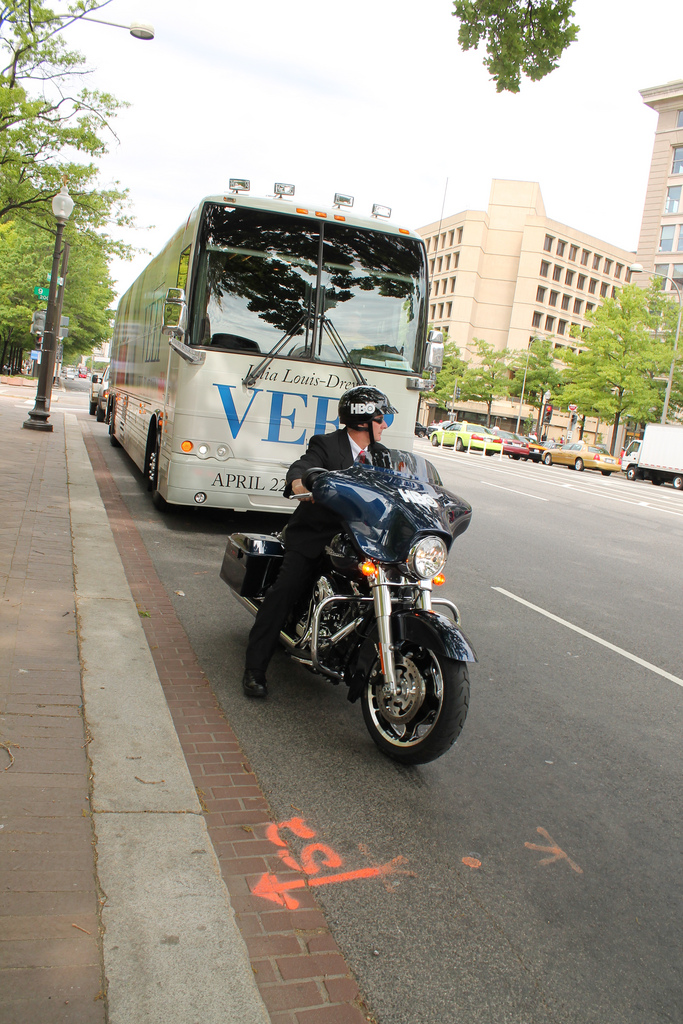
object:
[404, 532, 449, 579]
headlight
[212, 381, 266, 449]
writing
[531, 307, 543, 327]
window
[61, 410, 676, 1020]
street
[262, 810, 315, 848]
writing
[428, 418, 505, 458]
car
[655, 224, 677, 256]
window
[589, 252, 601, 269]
window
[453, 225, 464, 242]
window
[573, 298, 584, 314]
window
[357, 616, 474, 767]
wheel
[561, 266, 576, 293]
window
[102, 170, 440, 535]
bus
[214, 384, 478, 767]
motorcyclist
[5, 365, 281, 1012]
sidewalk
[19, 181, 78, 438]
lampost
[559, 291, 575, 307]
window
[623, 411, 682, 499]
truck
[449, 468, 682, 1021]
street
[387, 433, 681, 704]
road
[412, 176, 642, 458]
building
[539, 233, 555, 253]
window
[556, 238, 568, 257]
window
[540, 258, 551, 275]
window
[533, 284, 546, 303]
window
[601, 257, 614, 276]
window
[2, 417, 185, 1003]
sidewalk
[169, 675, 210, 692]
brick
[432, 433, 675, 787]
street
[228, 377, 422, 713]
man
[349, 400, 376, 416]
hbo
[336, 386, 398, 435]
helmet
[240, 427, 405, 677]
suit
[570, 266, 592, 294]
window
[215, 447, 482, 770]
motorcycle